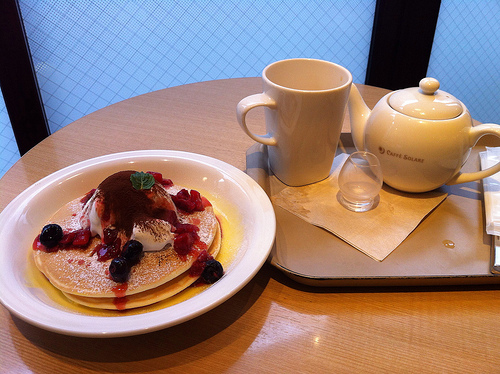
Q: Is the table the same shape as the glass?
A: Yes, both the table and the glass are round.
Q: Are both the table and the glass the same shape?
A: Yes, both the table and the glass are round.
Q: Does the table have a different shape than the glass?
A: No, both the table and the glass are round.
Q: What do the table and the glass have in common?
A: The shape, both the table and the glass are round.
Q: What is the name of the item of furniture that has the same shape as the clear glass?
A: The piece of furniture is a table.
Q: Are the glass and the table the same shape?
A: Yes, both the glass and the table are round.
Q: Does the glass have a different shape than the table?
A: No, both the glass and the table are round.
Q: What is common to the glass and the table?
A: The shape, both the glass and the table are round.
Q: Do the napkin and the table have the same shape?
A: No, the table is round and the napkin is square.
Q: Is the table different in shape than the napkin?
A: Yes, the table is round and the napkin is square.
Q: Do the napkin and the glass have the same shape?
A: No, the glass is round and the napkin is square.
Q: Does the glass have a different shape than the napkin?
A: Yes, the glass is round and the napkin is square.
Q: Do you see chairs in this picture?
A: No, there are no chairs.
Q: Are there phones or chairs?
A: No, there are no chairs or phones.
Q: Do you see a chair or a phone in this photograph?
A: No, there are no chairs or phones.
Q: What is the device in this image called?
A: The device is a screen.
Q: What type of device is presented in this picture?
A: The device is a screen.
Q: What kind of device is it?
A: The device is a screen.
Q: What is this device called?
A: This is a screen.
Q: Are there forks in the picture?
A: No, there are no forks.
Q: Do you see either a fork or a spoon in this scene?
A: No, there are no forks or spoons.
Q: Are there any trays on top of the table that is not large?
A: Yes, there is a tray on top of the table.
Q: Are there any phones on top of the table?
A: No, there is a tray on top of the table.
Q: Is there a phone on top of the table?
A: No, there is a tray on top of the table.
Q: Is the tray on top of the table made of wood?
A: Yes, the tray is on top of the table.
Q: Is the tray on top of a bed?
A: No, the tray is on top of the table.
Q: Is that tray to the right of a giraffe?
A: No, the tray is to the right of a fruit.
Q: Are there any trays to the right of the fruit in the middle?
A: Yes, there is a tray to the right of the fruit.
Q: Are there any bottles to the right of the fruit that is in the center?
A: No, there is a tray to the right of the fruit.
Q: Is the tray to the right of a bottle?
A: No, the tray is to the right of a fruit.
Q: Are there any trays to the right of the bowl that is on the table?
A: Yes, there is a tray to the right of the bowl.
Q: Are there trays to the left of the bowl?
A: No, the tray is to the right of the bowl.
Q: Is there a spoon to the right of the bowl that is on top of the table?
A: No, there is a tray to the right of the bowl.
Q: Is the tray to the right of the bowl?
A: Yes, the tray is to the right of the bowl.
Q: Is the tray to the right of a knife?
A: No, the tray is to the right of the bowl.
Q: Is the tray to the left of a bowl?
A: No, the tray is to the right of a bowl.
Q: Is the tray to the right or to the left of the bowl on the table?
A: The tray is to the right of the bowl.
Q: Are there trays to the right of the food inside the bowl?
A: Yes, there is a tray to the right of the food.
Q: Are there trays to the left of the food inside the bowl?
A: No, the tray is to the right of the food.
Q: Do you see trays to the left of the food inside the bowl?
A: No, the tray is to the right of the food.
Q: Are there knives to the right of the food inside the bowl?
A: No, there is a tray to the right of the food.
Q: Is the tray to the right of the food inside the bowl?
A: Yes, the tray is to the right of the food.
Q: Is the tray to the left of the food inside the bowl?
A: No, the tray is to the right of the food.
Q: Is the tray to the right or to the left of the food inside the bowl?
A: The tray is to the right of the food.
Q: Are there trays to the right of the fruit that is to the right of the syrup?
A: Yes, there is a tray to the right of the fruit.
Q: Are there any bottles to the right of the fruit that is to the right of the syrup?
A: No, there is a tray to the right of the fruit.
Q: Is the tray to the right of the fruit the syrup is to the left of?
A: Yes, the tray is to the right of the fruit.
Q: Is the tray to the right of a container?
A: No, the tray is to the right of the fruit.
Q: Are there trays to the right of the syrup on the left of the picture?
A: Yes, there is a tray to the right of the syrup.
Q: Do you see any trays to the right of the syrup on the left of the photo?
A: Yes, there is a tray to the right of the syrup.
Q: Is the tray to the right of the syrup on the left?
A: Yes, the tray is to the right of the syrup.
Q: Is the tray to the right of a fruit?
A: Yes, the tray is to the right of a fruit.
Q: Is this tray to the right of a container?
A: No, the tray is to the right of a fruit.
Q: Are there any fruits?
A: Yes, there is a fruit.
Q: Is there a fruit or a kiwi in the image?
A: Yes, there is a fruit.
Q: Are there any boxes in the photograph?
A: No, there are no boxes.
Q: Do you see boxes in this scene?
A: No, there are no boxes.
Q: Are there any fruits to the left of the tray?
A: Yes, there is a fruit to the left of the tray.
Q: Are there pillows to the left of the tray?
A: No, there is a fruit to the left of the tray.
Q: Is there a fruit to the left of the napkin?
A: Yes, there is a fruit to the left of the napkin.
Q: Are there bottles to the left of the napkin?
A: No, there is a fruit to the left of the napkin.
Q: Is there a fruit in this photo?
A: Yes, there is a fruit.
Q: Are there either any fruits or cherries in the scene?
A: Yes, there is a fruit.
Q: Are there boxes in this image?
A: No, there are no boxes.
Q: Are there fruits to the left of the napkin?
A: Yes, there is a fruit to the left of the napkin.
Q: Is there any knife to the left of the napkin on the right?
A: No, there is a fruit to the left of the napkin.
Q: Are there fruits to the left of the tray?
A: Yes, there is a fruit to the left of the tray.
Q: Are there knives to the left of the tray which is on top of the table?
A: No, there is a fruit to the left of the tray.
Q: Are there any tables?
A: Yes, there is a table.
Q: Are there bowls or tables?
A: Yes, there is a table.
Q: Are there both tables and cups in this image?
A: Yes, there are both a table and a cup.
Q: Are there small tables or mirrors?
A: Yes, there is a small table.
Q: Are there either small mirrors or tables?
A: Yes, there is a small table.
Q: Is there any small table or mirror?
A: Yes, there is a small table.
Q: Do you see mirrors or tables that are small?
A: Yes, the table is small.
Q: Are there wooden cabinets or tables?
A: Yes, there is a wood table.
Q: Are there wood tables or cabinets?
A: Yes, there is a wood table.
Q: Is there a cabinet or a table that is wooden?
A: Yes, the table is wooden.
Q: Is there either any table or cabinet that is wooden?
A: Yes, the table is wooden.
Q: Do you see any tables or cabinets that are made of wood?
A: Yes, the table is made of wood.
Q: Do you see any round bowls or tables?
A: Yes, there is a round table.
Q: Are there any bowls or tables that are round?
A: Yes, the table is round.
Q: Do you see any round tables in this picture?
A: Yes, there is a round table.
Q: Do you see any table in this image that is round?
A: Yes, there is a table that is round.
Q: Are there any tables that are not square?
A: Yes, there is a round table.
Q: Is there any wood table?
A: Yes, there is a table that is made of wood.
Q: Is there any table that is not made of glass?
A: Yes, there is a table that is made of wood.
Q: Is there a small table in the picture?
A: Yes, there is a small table.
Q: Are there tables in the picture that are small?
A: Yes, there is a small table.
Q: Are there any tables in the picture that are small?
A: Yes, there is a table that is small.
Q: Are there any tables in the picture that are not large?
A: Yes, there is a small table.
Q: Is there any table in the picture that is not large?
A: Yes, there is a small table.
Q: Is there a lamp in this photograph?
A: No, there are no lamps.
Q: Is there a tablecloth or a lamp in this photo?
A: No, there are no lamps or tablecloths.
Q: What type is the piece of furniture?
A: The piece of furniture is a table.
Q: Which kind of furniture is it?
A: The piece of furniture is a table.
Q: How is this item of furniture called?
A: This is a table.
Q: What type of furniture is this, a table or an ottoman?
A: This is a table.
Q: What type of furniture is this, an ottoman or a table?
A: This is a table.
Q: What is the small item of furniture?
A: The piece of furniture is a table.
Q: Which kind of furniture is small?
A: The furniture is a table.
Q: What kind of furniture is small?
A: The furniture is a table.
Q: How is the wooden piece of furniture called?
A: The piece of furniture is a table.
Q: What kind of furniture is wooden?
A: The furniture is a table.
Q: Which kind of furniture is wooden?
A: The furniture is a table.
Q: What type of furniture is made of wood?
A: The furniture is a table.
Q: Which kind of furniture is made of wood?
A: The furniture is a table.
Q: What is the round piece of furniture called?
A: The piece of furniture is a table.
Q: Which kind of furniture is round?
A: The furniture is a table.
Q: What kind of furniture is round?
A: The furniture is a table.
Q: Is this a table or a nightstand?
A: This is a table.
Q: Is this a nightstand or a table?
A: This is a table.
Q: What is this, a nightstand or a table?
A: This is a table.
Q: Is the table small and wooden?
A: Yes, the table is small and wooden.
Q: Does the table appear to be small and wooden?
A: Yes, the table is small and wooden.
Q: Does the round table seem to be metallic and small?
A: No, the table is small but wooden.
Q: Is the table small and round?
A: Yes, the table is small and round.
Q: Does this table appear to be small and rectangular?
A: No, the table is small but round.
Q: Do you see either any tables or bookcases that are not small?
A: No, there is a table but it is small.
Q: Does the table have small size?
A: Yes, the table is small.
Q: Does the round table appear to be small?
A: Yes, the table is small.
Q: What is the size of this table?
A: The table is small.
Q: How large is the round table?
A: The table is small.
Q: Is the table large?
A: No, the table is small.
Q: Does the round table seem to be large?
A: No, the table is small.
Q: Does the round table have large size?
A: No, the table is small.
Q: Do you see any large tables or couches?
A: No, there is a table but it is small.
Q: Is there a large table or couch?
A: No, there is a table but it is small.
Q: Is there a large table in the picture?
A: No, there is a table but it is small.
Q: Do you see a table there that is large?
A: No, there is a table but it is small.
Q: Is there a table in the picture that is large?
A: No, there is a table but it is small.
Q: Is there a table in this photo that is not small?
A: No, there is a table but it is small.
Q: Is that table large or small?
A: The table is small.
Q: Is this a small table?
A: Yes, this is a small table.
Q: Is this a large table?
A: No, this is a small table.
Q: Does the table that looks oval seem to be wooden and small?
A: Yes, the table is wooden and small.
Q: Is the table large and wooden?
A: No, the table is wooden but small.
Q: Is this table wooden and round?
A: Yes, the table is wooden and round.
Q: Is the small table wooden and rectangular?
A: No, the table is wooden but round.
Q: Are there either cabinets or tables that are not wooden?
A: No, there is a table but it is wooden.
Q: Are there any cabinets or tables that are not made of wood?
A: No, there is a table but it is made of wood.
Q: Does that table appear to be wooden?
A: Yes, the table is wooden.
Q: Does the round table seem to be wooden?
A: Yes, the table is wooden.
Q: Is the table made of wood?
A: Yes, the table is made of wood.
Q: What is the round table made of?
A: The table is made of wood.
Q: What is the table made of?
A: The table is made of wood.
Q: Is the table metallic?
A: No, the table is wooden.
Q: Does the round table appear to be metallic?
A: No, the table is wooden.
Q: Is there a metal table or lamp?
A: No, there is a table but it is wooden.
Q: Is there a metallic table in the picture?
A: No, there is a table but it is wooden.